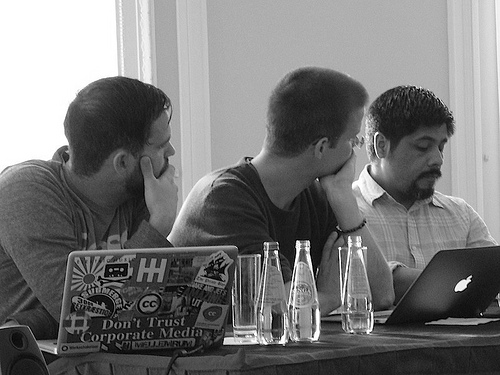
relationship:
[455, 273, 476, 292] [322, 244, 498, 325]
logo on laptop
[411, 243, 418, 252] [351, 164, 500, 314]
button on shirt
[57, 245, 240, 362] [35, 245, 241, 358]
back of laptop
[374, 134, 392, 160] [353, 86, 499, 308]
ear on man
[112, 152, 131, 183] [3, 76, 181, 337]
ear on man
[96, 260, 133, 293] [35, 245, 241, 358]
sticker on laptop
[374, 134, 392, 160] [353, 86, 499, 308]
ear of man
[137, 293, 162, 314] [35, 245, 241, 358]
sticker on laptop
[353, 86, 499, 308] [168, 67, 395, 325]
man sitting next to man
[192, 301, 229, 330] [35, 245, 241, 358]
sticker on laptop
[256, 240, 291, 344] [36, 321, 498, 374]
bottle on table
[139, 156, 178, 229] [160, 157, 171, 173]
hand on mouth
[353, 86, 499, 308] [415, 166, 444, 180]
man has mustache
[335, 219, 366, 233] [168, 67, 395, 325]
band on man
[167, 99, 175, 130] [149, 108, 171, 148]
hair laying on forehead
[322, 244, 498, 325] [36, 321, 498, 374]
laptop on table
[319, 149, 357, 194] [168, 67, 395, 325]
hand of man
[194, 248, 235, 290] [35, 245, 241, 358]
sticker on laptop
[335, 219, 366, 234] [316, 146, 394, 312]
band on arm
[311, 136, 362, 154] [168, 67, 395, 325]
glasses on man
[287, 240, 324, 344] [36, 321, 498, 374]
bottle on table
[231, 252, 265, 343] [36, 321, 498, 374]
glass on table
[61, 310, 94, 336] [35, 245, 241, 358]
sticker on laptop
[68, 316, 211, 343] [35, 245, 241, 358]
sticker on laptop